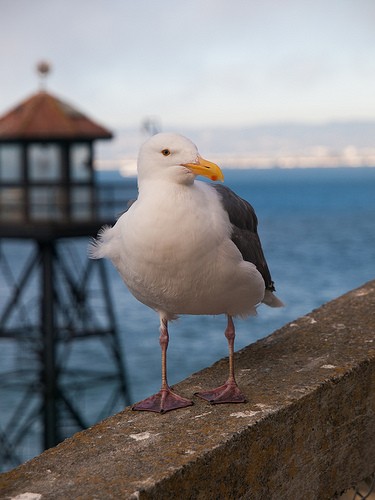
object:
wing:
[212, 182, 277, 290]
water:
[300, 164, 374, 223]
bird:
[84, 132, 283, 413]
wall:
[262, 378, 332, 472]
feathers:
[238, 208, 264, 280]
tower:
[2, 57, 135, 484]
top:
[2, 60, 113, 139]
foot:
[125, 382, 197, 417]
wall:
[340, 372, 373, 499]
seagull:
[87, 131, 284, 415]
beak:
[183, 158, 223, 182]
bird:
[83, 132, 290, 416]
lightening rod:
[33, 53, 49, 88]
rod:
[35, 60, 50, 90]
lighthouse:
[0, 61, 137, 470]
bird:
[86, 128, 289, 418]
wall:
[180, 368, 246, 493]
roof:
[3, 60, 112, 145]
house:
[1, 90, 114, 228]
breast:
[146, 219, 221, 300]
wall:
[296, 314, 363, 395]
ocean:
[309, 165, 372, 259]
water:
[282, 207, 322, 259]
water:
[119, 297, 152, 387]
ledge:
[1, 279, 373, 498]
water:
[282, 257, 309, 318]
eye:
[158, 147, 171, 155]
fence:
[335, 436, 373, 497]